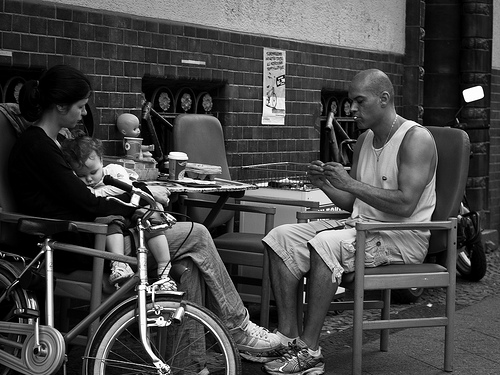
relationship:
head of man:
[337, 55, 395, 133] [253, 62, 460, 372]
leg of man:
[295, 218, 412, 360] [262, 66, 441, 367]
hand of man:
[321, 159, 357, 189] [239, 55, 452, 373]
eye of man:
[357, 92, 367, 103] [253, 62, 460, 372]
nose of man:
[352, 96, 362, 111] [239, 55, 452, 373]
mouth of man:
[352, 111, 362, 125] [253, 62, 460, 372]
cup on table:
[167, 151, 189, 181] [93, 120, 288, 271]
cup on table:
[158, 140, 190, 180] [114, 143, 300, 277]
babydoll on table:
[109, 109, 175, 180] [126, 135, 333, 333]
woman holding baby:
[9, 50, 272, 372] [58, 129, 178, 292]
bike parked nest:
[5, 190, 229, 370] [2, 183, 158, 337]